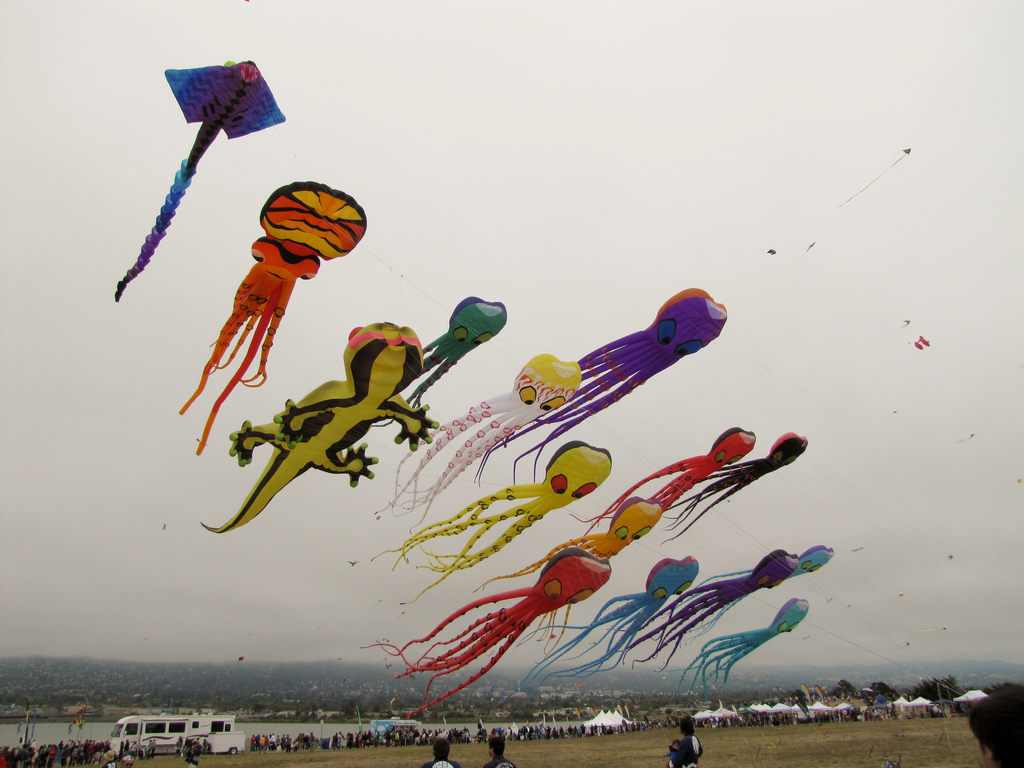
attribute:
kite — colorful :
[113, 57, 287, 305]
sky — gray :
[369, 11, 1005, 324]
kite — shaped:
[301, 324, 439, 455]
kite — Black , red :
[575, 430, 756, 529]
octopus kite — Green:
[415, 282, 514, 399]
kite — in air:
[409, 532, 615, 701]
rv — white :
[121, 708, 226, 757]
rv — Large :
[113, 700, 232, 759]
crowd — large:
[252, 664, 965, 768]